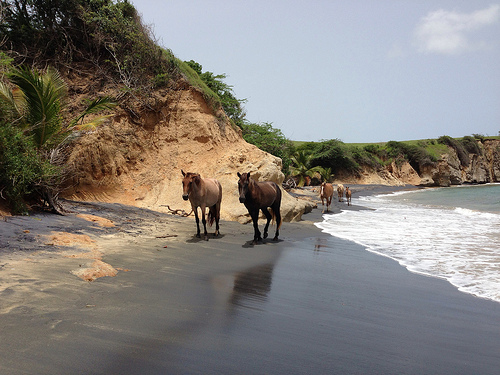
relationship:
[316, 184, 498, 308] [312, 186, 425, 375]
water coming to shore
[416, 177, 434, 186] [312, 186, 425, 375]
rock on shore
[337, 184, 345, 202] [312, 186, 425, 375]
horse on shore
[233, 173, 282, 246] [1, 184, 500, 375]
horse on beach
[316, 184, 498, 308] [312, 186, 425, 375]
water washing up on shore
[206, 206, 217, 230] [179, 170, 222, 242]
tail of horse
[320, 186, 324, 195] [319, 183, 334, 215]
marking on horse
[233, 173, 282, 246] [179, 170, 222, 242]
horse walking beside a horse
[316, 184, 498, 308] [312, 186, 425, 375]
water crashing on shore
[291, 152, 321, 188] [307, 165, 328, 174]
fern with large leaves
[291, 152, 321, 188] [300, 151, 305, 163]
fern with large leaves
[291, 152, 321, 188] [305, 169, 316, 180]
fern with large leaves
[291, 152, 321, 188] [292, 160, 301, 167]
fern with large leaves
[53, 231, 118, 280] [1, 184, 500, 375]
sand on beach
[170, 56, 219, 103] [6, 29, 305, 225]
grass on cliff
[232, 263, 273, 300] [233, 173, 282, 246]
reflection of horse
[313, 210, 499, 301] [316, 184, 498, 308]
foam on water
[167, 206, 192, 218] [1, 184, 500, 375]
branch on beach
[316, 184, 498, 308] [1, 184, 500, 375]
water crashing to beach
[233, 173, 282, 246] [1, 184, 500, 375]
horse on wet beach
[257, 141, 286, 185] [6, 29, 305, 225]
rock on cliff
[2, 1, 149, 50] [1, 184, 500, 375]
tree behind beach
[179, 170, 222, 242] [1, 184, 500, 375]
horse on beach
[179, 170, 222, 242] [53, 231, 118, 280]
horse in sand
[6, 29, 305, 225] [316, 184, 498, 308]
cliff by water